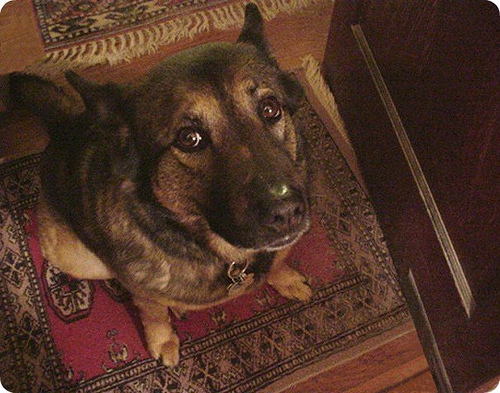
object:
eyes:
[168, 127, 210, 153]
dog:
[0, 3, 323, 371]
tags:
[225, 272, 257, 299]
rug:
[2, 52, 421, 393]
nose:
[261, 199, 308, 233]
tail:
[0, 69, 85, 137]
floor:
[0, 0, 439, 393]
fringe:
[23, 0, 314, 78]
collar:
[222, 256, 255, 297]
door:
[317, 0, 500, 393]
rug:
[26, 0, 327, 79]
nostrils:
[272, 215, 286, 224]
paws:
[142, 334, 187, 371]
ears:
[234, 2, 273, 48]